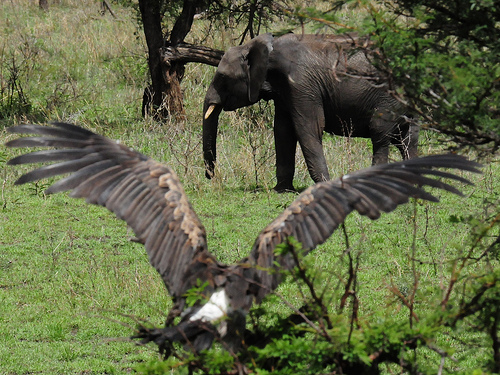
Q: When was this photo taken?
A: Day time.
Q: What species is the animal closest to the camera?
A: A bird.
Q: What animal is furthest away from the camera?
A: An elephant.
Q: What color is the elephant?
A: Gray.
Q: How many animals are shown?
A: Two.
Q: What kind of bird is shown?
A: A vulture.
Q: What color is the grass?
A: Green.